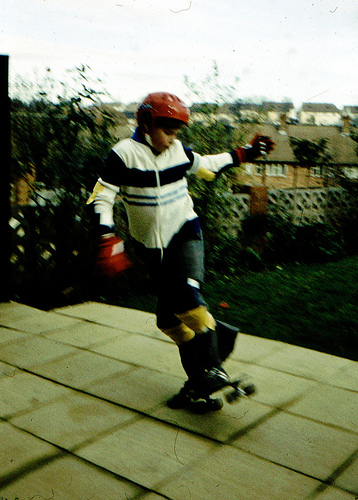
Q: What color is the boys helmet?
A: Red.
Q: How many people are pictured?
A: One.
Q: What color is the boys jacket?
A: Black and white, and blue.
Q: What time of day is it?
A: Daytime.